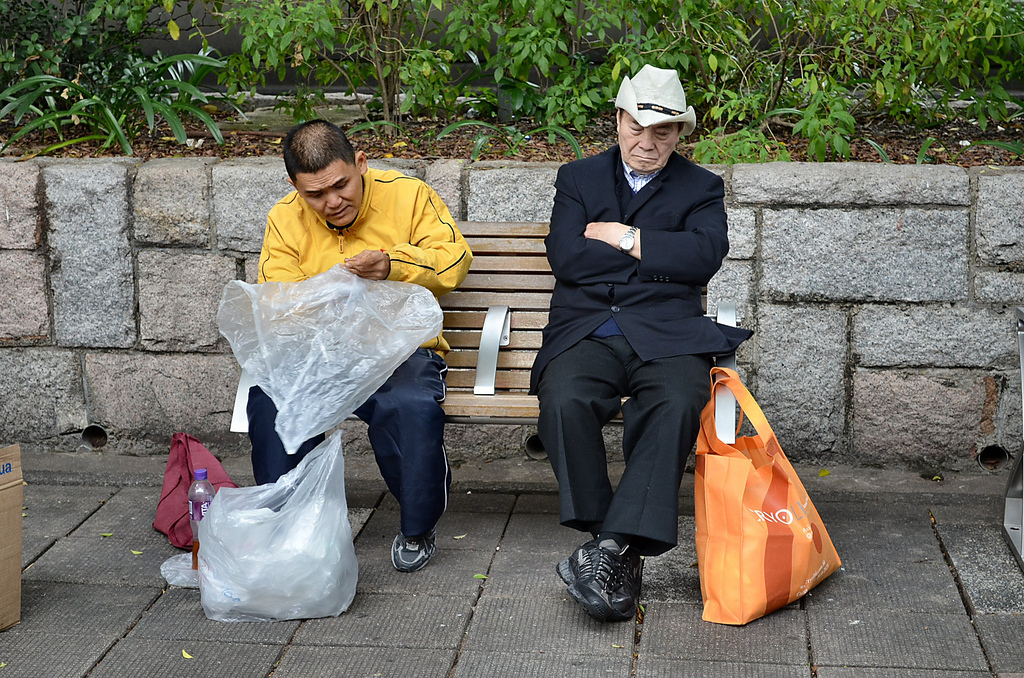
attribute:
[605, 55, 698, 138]
hat — white, new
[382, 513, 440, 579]
shoes — black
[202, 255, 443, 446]
bag — white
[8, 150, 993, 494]
wall — grey, short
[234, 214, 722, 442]
bench — brown, small, wooden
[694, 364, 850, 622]
bag — orange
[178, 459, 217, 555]
bottle — plastic, closed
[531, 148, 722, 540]
suit — black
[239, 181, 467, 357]
shirt — yellow, dark yellow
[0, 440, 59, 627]
box — brown, small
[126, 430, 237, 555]
bag — red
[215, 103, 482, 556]
man — brown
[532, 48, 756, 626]
man — old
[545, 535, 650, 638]
sneakers — black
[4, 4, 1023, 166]
hedges — green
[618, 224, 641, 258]
watch — gold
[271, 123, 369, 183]
hair — short